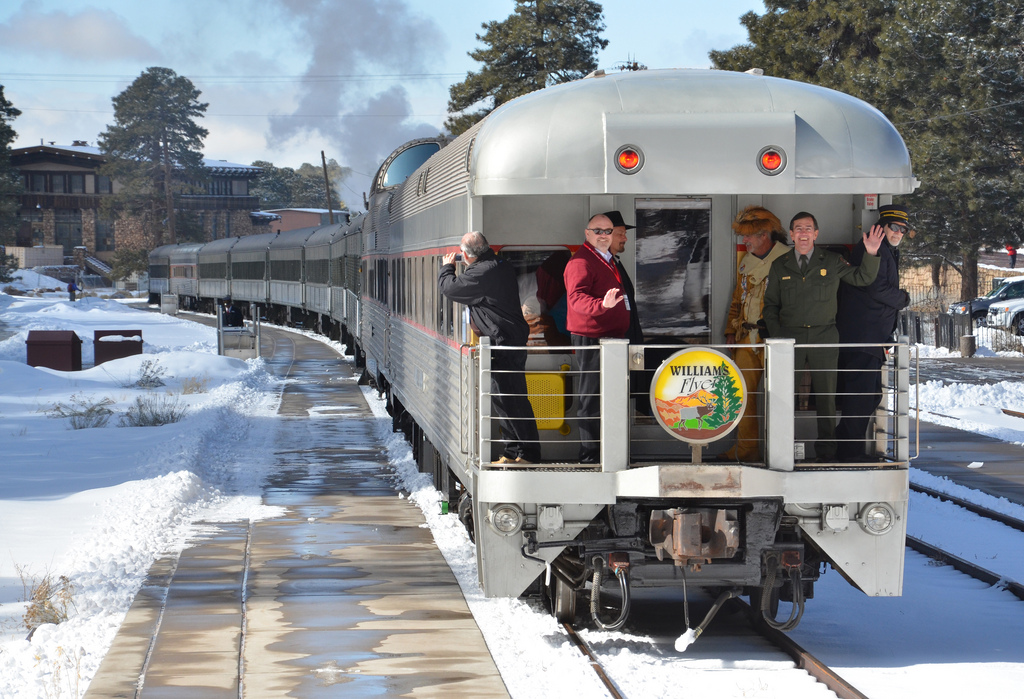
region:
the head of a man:
[579, 213, 614, 258]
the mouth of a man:
[596, 239, 609, 249]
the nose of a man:
[596, 230, 613, 240]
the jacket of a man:
[555, 248, 629, 344]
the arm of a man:
[561, 262, 604, 319]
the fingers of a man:
[596, 280, 626, 306]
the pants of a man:
[564, 324, 607, 458]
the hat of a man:
[601, 205, 634, 238]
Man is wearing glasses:
[563, 207, 639, 344]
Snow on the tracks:
[503, 596, 914, 696]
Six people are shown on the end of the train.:
[450, 201, 928, 361]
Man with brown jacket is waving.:
[763, 206, 882, 333]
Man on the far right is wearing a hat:
[861, 193, 915, 342]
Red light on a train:
[615, 142, 642, 174]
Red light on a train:
[760, 145, 786, 177]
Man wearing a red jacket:
[561, 247, 626, 336]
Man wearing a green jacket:
[759, 241, 883, 346]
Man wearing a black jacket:
[835, 243, 908, 346]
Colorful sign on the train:
[648, 347, 750, 446]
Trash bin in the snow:
[23, 328, 84, 371]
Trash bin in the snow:
[93, 325, 145, 370]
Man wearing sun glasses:
[586, 222, 615, 238]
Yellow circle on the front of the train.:
[626, 338, 775, 463]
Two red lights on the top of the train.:
[585, 142, 860, 200]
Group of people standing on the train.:
[520, 209, 929, 443]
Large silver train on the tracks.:
[175, 160, 918, 587]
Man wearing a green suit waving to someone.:
[781, 206, 900, 320]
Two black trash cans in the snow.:
[2, 294, 168, 399]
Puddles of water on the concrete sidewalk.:
[216, 502, 452, 692]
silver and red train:
[140, 67, 929, 605]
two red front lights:
[611, 143, 793, 176]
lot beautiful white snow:
[1, 267, 1022, 695]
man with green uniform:
[751, 210, 885, 458]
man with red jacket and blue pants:
[561, 210, 637, 466]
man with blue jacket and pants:
[434, 225, 551, 464]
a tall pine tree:
[91, 64, 212, 243]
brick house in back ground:
[1, 140, 271, 261]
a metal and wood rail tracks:
[535, 472, 1022, 695]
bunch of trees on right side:
[709, 0, 1022, 329]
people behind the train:
[442, 80, 935, 528]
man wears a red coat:
[558, 213, 643, 370]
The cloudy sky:
[8, 0, 811, 175]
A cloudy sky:
[11, 9, 743, 207]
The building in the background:
[6, 105, 338, 303]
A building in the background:
[4, 115, 355, 330]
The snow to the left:
[0, 235, 282, 689]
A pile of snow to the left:
[14, 243, 163, 687]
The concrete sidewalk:
[121, 257, 450, 694]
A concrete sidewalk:
[102, 237, 502, 694]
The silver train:
[119, 57, 925, 617]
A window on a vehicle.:
[637, 198, 713, 417]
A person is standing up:
[565, 213, 627, 461]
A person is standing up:
[439, 231, 544, 462]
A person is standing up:
[720, 204, 790, 462]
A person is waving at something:
[758, 209, 883, 457]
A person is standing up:
[836, 206, 912, 463]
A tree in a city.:
[98, 64, 212, 239]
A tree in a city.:
[449, 1, 609, 138]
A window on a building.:
[68, 171, 87, 192]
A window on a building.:
[28, 172, 48, 192]